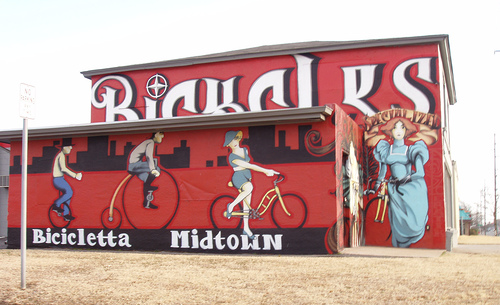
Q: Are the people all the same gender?
A: No, they are both male and female.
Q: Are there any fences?
A: No, there are no fences.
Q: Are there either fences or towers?
A: No, there are no fences or towers.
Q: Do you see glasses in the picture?
A: No, there are no glasses.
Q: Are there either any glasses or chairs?
A: No, there are no glasses or chairs.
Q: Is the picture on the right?
A: Yes, the picture is on the right of the image.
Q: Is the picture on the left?
A: No, the picture is on the right of the image.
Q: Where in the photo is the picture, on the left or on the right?
A: The picture is on the right of the image.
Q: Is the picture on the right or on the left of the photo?
A: The picture is on the right of the image.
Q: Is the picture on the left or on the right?
A: The picture is on the right of the image.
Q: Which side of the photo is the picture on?
A: The picture is on the right of the image.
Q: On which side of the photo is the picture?
A: The picture is on the right of the image.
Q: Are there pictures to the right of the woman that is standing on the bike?
A: Yes, there is a picture to the right of the woman.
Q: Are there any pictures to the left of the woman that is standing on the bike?
A: No, the picture is to the right of the woman.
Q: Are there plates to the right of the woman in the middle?
A: No, there is a picture to the right of the woman.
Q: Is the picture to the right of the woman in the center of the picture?
A: Yes, the picture is to the right of the woman.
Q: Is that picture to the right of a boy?
A: No, the picture is to the right of the woman.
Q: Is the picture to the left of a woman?
A: No, the picture is to the right of a woman.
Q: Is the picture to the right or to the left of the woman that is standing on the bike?
A: The picture is to the right of the woman.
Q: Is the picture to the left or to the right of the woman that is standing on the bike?
A: The picture is to the right of the woman.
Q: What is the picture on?
A: The picture is on the wall.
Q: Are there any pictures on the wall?
A: Yes, there is a picture on the wall.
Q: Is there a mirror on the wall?
A: No, there is a picture on the wall.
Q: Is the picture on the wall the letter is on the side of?
A: Yes, the picture is on the wall.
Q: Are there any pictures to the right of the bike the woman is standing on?
A: Yes, there is a picture to the right of the bike.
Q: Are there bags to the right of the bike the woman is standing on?
A: No, there is a picture to the right of the bike.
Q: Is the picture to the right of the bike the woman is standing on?
A: Yes, the picture is to the right of the bike.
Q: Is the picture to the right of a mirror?
A: No, the picture is to the right of the bike.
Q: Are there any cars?
A: No, there are no cars.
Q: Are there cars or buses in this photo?
A: No, there are no cars or buses.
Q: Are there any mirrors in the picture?
A: No, there are no mirrors.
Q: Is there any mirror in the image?
A: No, there are no mirrors.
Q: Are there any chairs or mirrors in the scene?
A: No, there are no mirrors or chairs.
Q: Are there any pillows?
A: No, there are no pillows.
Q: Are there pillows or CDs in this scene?
A: No, there are no pillows or cds.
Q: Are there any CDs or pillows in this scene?
A: No, there are no pillows or cds.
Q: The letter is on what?
A: The letter is on the wall.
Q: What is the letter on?
A: The letter is on the wall.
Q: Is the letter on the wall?
A: Yes, the letter is on the wall.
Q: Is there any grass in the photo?
A: Yes, there is grass.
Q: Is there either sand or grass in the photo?
A: Yes, there is grass.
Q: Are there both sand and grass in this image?
A: No, there is grass but no sand.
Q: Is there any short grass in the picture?
A: Yes, there is short grass.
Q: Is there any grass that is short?
A: Yes, there is short grass.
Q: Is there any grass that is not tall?
A: Yes, there is short grass.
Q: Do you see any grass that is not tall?
A: Yes, there is short grass.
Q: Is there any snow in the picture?
A: No, there is no snow.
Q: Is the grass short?
A: Yes, the grass is short.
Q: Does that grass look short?
A: Yes, the grass is short.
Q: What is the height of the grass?
A: The grass is short.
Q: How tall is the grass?
A: The grass is short.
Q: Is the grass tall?
A: No, the grass is short.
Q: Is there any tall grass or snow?
A: No, there is grass but it is short.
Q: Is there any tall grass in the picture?
A: No, there is grass but it is short.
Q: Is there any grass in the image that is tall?
A: No, there is grass but it is short.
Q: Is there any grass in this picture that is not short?
A: No, there is grass but it is short.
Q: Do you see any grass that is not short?
A: No, there is grass but it is short.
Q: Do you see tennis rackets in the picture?
A: No, there are no tennis rackets.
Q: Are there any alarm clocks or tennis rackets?
A: No, there are no tennis rackets or alarm clocks.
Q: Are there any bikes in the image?
A: Yes, there is a bike.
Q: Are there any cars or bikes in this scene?
A: Yes, there is a bike.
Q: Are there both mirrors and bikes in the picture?
A: No, there is a bike but no mirrors.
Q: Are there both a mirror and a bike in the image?
A: No, there is a bike but no mirrors.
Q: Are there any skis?
A: No, there are no skis.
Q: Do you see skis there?
A: No, there are no skis.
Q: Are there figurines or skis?
A: No, there are no skis or figurines.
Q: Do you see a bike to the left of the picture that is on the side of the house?
A: Yes, there is a bike to the left of the picture.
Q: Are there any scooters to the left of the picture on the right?
A: No, there is a bike to the left of the picture.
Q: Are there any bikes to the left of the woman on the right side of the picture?
A: Yes, there is a bike to the left of the woman.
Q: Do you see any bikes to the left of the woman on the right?
A: Yes, there is a bike to the left of the woman.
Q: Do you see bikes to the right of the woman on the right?
A: No, the bike is to the left of the woman.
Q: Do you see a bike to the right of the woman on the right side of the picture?
A: No, the bike is to the left of the woman.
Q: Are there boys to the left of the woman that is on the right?
A: No, there is a bike to the left of the woman.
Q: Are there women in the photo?
A: Yes, there is a woman.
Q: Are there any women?
A: Yes, there is a woman.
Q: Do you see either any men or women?
A: Yes, there is a woman.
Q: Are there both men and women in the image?
A: Yes, there are both a woman and a man.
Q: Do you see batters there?
A: No, there are no batters.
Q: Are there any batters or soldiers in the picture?
A: No, there are no batters or soldiers.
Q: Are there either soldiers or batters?
A: No, there are no batters or soldiers.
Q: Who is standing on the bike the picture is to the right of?
A: The woman is standing on the bike.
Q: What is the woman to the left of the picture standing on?
A: The woman is standing on the bike.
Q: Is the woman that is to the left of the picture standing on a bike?
A: Yes, the woman is standing on a bike.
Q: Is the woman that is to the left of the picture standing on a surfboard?
A: No, the woman is standing on a bike.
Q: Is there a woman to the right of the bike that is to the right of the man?
A: Yes, there is a woman to the right of the bike.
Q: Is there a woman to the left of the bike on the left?
A: No, the woman is to the right of the bike.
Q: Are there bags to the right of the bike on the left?
A: No, there is a woman to the right of the bike.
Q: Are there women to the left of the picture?
A: Yes, there is a woman to the left of the picture.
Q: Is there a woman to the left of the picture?
A: Yes, there is a woman to the left of the picture.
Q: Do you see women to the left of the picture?
A: Yes, there is a woman to the left of the picture.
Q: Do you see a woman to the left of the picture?
A: Yes, there is a woman to the left of the picture.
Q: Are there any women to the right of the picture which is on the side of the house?
A: No, the woman is to the left of the picture.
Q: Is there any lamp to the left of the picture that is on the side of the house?
A: No, there is a woman to the left of the picture.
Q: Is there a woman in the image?
A: Yes, there is a woman.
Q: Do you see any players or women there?
A: Yes, there is a woman.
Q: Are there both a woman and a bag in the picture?
A: No, there is a woman but no bags.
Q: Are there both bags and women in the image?
A: No, there is a woman but no bags.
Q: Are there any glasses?
A: No, there are no glasses.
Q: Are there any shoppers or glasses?
A: No, there are no glasses or shoppers.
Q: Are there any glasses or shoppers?
A: No, there are no glasses or shoppers.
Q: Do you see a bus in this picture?
A: No, there are no buses.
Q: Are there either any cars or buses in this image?
A: No, there are no buses or cars.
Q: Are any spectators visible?
A: No, there are no spectators.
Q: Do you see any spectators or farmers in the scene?
A: No, there are no spectators or farmers.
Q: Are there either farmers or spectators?
A: No, there are no spectators or farmers.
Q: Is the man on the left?
A: Yes, the man is on the left of the image.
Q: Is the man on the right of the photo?
A: No, the man is on the left of the image.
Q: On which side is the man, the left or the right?
A: The man is on the left of the image.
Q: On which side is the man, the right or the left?
A: The man is on the left of the image.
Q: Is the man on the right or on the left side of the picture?
A: The man is on the left of the image.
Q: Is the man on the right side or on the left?
A: The man is on the left of the image.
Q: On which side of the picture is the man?
A: The man is on the left of the image.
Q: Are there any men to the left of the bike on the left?
A: Yes, there is a man to the left of the bike.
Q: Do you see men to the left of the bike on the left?
A: Yes, there is a man to the left of the bike.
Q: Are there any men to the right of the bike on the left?
A: No, the man is to the left of the bike.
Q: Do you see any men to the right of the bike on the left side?
A: No, the man is to the left of the bike.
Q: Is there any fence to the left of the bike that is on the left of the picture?
A: No, there is a man to the left of the bike.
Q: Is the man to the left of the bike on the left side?
A: Yes, the man is to the left of the bike.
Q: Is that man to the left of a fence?
A: No, the man is to the left of the bike.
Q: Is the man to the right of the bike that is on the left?
A: No, the man is to the left of the bike.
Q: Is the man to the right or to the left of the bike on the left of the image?
A: The man is to the left of the bike.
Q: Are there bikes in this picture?
A: Yes, there is a bike.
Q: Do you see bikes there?
A: Yes, there is a bike.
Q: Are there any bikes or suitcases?
A: Yes, there is a bike.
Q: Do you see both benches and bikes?
A: No, there is a bike but no benches.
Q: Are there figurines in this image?
A: No, there are no figurines.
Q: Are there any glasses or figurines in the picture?
A: No, there are no figurines or glasses.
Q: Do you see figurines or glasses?
A: No, there are no figurines or glasses.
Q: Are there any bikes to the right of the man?
A: Yes, there is a bike to the right of the man.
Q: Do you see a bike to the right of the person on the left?
A: Yes, there is a bike to the right of the man.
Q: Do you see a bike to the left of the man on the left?
A: No, the bike is to the right of the man.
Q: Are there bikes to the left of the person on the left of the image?
A: No, the bike is to the right of the man.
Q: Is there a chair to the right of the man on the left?
A: No, there is a bike to the right of the man.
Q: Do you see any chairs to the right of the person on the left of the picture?
A: No, there is a bike to the right of the man.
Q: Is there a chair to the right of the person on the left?
A: No, there is a bike to the right of the man.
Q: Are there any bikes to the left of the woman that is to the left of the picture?
A: Yes, there is a bike to the left of the woman.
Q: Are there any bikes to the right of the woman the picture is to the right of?
A: No, the bike is to the left of the woman.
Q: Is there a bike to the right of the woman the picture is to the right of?
A: No, the bike is to the left of the woman.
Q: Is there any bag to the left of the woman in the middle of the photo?
A: No, there is a bike to the left of the woman.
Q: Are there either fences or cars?
A: No, there are no cars or fences.